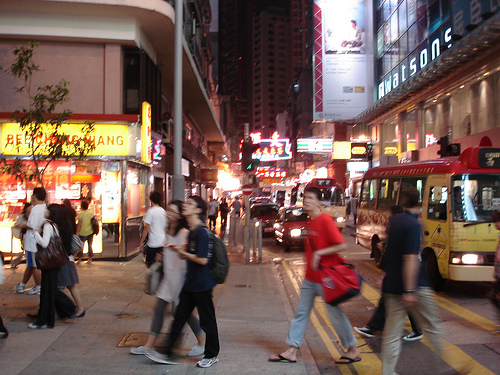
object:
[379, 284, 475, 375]
tan pants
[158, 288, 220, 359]
black pants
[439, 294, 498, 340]
line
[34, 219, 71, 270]
bag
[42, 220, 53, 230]
shoulder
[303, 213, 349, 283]
shirt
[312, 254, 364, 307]
bag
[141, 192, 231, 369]
man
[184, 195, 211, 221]
hair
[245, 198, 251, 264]
post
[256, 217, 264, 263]
post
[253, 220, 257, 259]
post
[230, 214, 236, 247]
post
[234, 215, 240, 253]
post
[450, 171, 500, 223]
windshield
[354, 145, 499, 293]
bus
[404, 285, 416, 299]
wrist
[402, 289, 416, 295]
watch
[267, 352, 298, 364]
slippers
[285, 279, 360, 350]
pants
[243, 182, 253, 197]
sign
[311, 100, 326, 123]
edge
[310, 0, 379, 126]
billboard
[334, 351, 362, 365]
flip flops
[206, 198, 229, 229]
people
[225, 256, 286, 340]
sidewalk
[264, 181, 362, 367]
man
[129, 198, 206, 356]
woman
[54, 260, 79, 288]
skirt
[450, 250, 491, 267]
headlight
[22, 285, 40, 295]
shoes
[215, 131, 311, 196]
sign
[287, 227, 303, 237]
headlight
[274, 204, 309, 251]
car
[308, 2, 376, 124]
light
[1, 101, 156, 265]
light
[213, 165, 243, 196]
light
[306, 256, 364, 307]
bag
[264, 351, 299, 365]
black sandals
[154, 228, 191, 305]
grey tights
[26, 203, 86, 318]
woman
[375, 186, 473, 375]
person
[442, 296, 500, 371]
street